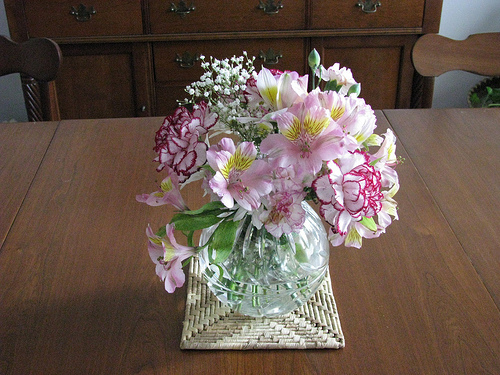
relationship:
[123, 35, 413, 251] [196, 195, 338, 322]
flowers in vase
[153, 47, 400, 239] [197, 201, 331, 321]
flowers in vase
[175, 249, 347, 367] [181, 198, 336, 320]
mat under vase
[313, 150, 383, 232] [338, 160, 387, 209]
flower with tips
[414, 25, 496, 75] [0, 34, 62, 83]
tops to chair back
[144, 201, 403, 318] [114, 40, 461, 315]
vase of flowers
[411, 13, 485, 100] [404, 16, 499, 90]
back of chair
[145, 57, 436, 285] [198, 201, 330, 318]
flowers in vase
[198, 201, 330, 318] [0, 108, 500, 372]
vase on board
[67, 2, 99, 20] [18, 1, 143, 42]
handle on drawer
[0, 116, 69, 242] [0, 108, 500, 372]
crack in board